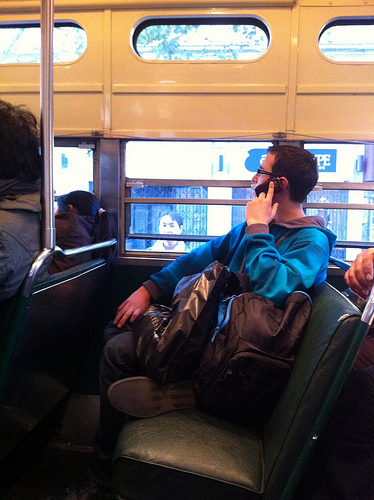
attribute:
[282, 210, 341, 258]
hood — flipped back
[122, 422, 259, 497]
seat — green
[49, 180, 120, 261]
woman — leaning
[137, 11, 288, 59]
window — oblong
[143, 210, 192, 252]
man — looking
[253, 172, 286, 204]
cell phone — black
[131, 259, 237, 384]
bag — shopping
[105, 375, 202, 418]
sole — black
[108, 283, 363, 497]
seat — leather